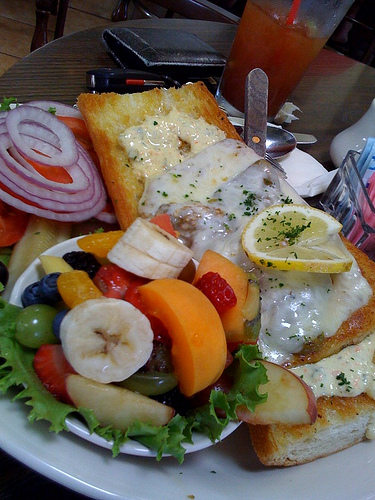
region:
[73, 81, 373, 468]
fish on a plate covered in sauce.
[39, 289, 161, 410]
a banana slice on a plate.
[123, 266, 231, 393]
a slice of fruit on a plate.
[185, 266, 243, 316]
a berry next to other fruit.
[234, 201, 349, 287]
a lemon wedge with parsley.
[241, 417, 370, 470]
the cut edge of a piece of fish.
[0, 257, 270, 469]
a piece of lettuce in a bowl.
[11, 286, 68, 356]
a green grape.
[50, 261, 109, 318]
an orange slice.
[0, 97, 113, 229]
a slice of an onion.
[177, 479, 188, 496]
the plate is white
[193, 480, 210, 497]
the plate is white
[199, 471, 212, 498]
the plate is white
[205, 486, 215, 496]
the plate is white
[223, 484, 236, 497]
the plate is white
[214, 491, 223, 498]
the plate is white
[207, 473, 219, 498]
the plate is white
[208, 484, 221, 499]
the plate is white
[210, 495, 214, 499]
the plate is white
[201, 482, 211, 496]
the plate is white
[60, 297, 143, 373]
piece of banana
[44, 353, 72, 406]
piece of strawberry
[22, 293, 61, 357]
a green grape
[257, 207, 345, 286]
lemon slice on top of cheese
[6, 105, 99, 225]
red onion rings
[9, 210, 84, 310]
pickle spear by the onion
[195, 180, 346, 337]
melted cheese on the bread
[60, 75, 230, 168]
toasted bread on the plate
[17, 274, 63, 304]
blueberries on the plate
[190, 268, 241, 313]
raspberry on the plate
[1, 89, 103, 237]
Uncooked onion rings on top of tomato slices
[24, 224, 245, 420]
Fresh fruit salad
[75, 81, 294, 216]
Garlic bread with sauce and condiments on it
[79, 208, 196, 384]
Round banana slices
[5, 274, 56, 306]
Blueberries used in a fruit salad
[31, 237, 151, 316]
Slices of apple, orange, banana and blackberries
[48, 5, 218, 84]
Wallet on wooden table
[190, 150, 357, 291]
Lemon slice on fish covered in sauce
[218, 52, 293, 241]
Wooden utensil handle behind food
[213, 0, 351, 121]
Glass with orange drink and straw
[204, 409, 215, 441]
the lettuce is green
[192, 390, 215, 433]
the lettuce is green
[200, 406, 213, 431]
the lettuce is green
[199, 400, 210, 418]
the lettuce is green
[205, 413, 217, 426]
the lettuce is green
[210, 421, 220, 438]
the lettuce is green